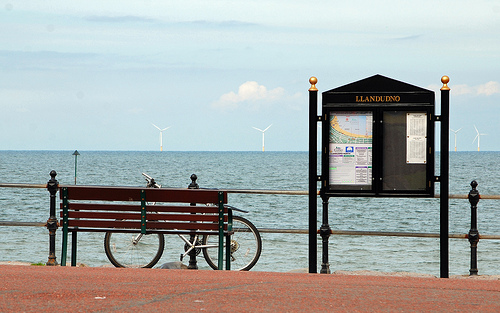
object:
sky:
[0, 0, 500, 152]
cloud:
[200, 78, 499, 115]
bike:
[103, 171, 262, 271]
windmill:
[249, 123, 274, 152]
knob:
[438, 74, 451, 90]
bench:
[57, 183, 235, 270]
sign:
[404, 112, 426, 164]